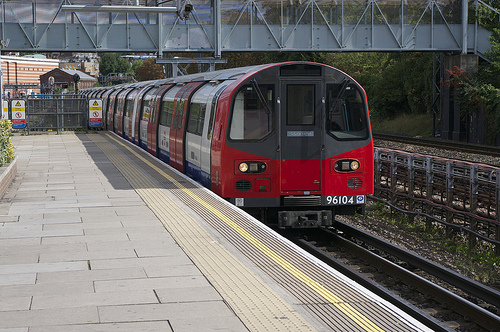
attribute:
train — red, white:
[70, 59, 378, 234]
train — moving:
[0, 55, 377, 231]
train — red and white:
[134, 45, 371, 192]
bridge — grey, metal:
[0, 1, 499, 51]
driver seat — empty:
[320, 92, 354, 137]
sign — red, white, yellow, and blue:
[87, 97, 104, 126]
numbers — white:
[322, 192, 356, 206]